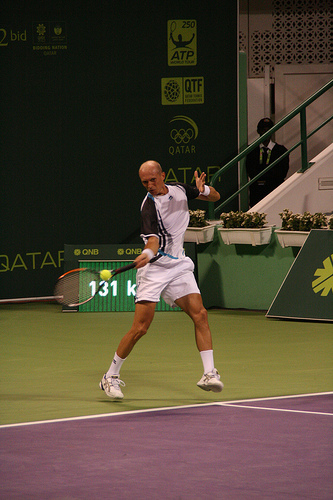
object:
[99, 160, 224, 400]
man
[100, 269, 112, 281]
tennis ball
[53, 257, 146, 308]
racquet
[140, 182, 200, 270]
shirt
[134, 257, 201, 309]
shorts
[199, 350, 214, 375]
sock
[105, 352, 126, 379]
sock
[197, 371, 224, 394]
tennis shoe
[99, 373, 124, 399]
tennis shoe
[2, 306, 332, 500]
ground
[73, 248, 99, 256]
sign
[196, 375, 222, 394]
foot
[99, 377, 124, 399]
foot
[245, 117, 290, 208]
man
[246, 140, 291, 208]
suit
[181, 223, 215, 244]
planter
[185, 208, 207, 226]
flowers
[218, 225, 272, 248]
planter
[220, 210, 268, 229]
flowers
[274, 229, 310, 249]
planter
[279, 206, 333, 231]
flowers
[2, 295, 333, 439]
section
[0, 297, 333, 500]
tennis court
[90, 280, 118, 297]
number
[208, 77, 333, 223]
railing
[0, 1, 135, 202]
wall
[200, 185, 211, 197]
wrist band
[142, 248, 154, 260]
wrist band